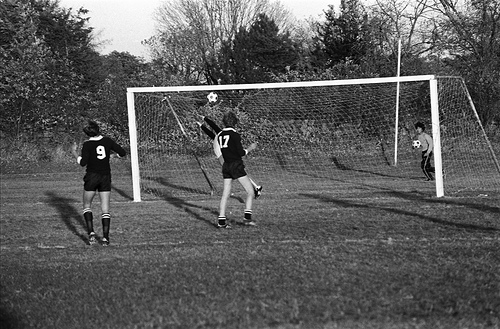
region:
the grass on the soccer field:
[238, 241, 391, 302]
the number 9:
[90, 145, 108, 161]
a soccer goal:
[286, 92, 376, 174]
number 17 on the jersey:
[212, 130, 227, 147]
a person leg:
[220, 181, 226, 217]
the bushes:
[15, 38, 75, 108]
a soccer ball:
[195, 90, 220, 105]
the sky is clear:
[107, 12, 137, 37]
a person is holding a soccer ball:
[410, 137, 420, 147]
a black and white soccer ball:
[411, 138, 422, 149]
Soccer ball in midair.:
[202, 90, 221, 106]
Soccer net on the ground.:
[114, 60, 499, 209]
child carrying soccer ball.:
[405, 117, 441, 181]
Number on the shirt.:
[90, 142, 107, 162]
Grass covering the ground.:
[0, 153, 497, 323]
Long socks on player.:
[76, 203, 118, 245]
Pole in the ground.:
[385, 34, 405, 166]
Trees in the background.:
[2, 0, 497, 167]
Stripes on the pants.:
[419, 147, 436, 181]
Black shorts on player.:
[68, 116, 130, 198]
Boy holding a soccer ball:
[408, 118, 436, 183]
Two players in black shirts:
[75, 111, 256, 246]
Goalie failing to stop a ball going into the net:
[192, 87, 261, 201]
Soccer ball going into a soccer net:
[202, 88, 219, 104]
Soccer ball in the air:
[203, 88, 222, 108]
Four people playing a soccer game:
[75, 109, 437, 242]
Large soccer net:
[122, 73, 498, 205]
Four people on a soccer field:
[75, 109, 438, 245]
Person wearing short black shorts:
[212, 108, 257, 231]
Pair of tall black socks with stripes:
[81, 203, 111, 240]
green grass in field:
[256, 274, 295, 302]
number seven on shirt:
[220, 133, 230, 146]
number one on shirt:
[216, 138, 224, 149]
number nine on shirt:
[93, 145, 110, 160]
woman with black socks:
[84, 216, 94, 228]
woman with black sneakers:
[84, 229, 115, 247]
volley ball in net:
[201, 88, 225, 105]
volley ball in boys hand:
[406, 137, 423, 152]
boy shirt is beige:
[421, 137, 428, 142]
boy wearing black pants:
[421, 156, 428, 165]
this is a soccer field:
[171, 146, 281, 206]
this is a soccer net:
[137, 74, 197, 165]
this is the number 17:
[195, 147, 247, 169]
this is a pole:
[415, 81, 447, 236]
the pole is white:
[412, 123, 459, 208]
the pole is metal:
[345, 80, 363, 104]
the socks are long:
[80, 228, 137, 244]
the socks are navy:
[51, 192, 180, 259]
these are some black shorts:
[192, 157, 275, 194]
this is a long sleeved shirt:
[70, 144, 159, 207]